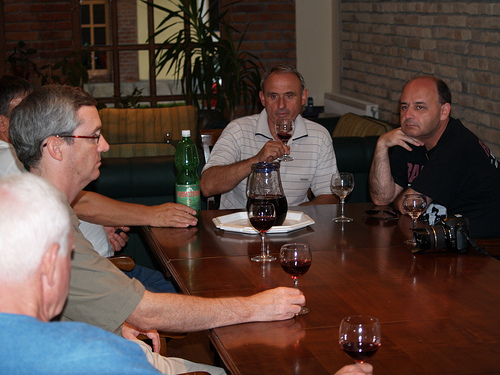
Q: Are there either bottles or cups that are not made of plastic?
A: No, there is a bottle but it is made of plastic.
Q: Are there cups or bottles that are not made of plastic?
A: No, there is a bottle but it is made of plastic.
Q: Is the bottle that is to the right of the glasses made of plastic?
A: Yes, the bottle is made of plastic.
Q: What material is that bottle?
A: The bottle is made of plastic.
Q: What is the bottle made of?
A: The bottle is made of plastic.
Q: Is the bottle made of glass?
A: No, the bottle is made of plastic.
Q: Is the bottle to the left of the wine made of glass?
A: No, the bottle is made of plastic.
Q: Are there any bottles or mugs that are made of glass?
A: No, there is a bottle but it is made of plastic.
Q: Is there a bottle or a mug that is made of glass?
A: No, there is a bottle but it is made of plastic.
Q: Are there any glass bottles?
A: No, there is a bottle but it is made of plastic.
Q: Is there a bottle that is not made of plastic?
A: No, there is a bottle but it is made of plastic.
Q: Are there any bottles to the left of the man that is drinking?
A: Yes, there is a bottle to the left of the man.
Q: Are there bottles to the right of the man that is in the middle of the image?
A: No, the bottle is to the left of the man.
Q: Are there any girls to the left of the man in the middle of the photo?
A: No, there is a bottle to the left of the man.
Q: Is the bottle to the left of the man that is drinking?
A: Yes, the bottle is to the left of the man.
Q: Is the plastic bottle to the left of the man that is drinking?
A: Yes, the bottle is to the left of the man.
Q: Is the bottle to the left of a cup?
A: No, the bottle is to the left of the man.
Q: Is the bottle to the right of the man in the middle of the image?
A: No, the bottle is to the left of the man.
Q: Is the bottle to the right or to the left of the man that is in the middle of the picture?
A: The bottle is to the left of the man.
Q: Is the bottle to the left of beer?
A: No, the bottle is to the left of the wine.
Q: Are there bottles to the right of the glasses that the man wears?
A: Yes, there is a bottle to the right of the glasses.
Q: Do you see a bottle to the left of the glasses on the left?
A: No, the bottle is to the right of the glasses.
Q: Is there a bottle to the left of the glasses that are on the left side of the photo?
A: No, the bottle is to the right of the glasses.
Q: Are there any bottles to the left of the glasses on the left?
A: No, the bottle is to the right of the glasses.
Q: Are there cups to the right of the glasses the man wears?
A: No, there is a bottle to the right of the glasses.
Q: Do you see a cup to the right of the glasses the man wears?
A: No, there is a bottle to the right of the glasses.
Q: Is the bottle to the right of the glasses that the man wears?
A: Yes, the bottle is to the right of the glasses.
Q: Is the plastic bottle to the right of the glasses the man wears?
A: Yes, the bottle is to the right of the glasses.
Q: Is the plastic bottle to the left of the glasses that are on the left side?
A: No, the bottle is to the right of the glasses.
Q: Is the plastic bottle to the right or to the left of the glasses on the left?
A: The bottle is to the right of the glasses.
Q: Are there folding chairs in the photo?
A: No, there are no folding chairs.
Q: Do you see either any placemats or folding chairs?
A: No, there are no folding chairs or placemats.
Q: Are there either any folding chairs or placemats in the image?
A: No, there are no folding chairs or placemats.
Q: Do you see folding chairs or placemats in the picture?
A: No, there are no folding chairs or placemats.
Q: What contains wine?
A: The glass contains wine.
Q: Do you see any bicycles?
A: No, there are no bicycles.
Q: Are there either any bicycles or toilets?
A: No, there are no bicycles or toilets.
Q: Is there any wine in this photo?
A: Yes, there is wine.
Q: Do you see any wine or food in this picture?
A: Yes, there is wine.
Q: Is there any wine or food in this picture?
A: Yes, there is wine.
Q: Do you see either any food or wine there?
A: Yes, there is wine.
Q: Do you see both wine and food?
A: No, there is wine but no food.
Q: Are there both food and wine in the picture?
A: No, there is wine but no food.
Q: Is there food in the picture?
A: No, there is no food.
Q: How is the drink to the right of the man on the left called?
A: The drink is wine.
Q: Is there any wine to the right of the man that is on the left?
A: Yes, there is wine to the right of the man.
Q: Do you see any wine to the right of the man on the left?
A: Yes, there is wine to the right of the man.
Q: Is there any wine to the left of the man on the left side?
A: No, the wine is to the right of the man.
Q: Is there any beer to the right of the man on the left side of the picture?
A: No, there is wine to the right of the man.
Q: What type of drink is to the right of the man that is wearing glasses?
A: The drink is wine.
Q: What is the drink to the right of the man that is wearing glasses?
A: The drink is wine.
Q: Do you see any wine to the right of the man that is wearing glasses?
A: Yes, there is wine to the right of the man.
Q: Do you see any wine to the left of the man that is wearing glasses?
A: No, the wine is to the right of the man.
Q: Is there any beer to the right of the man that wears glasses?
A: No, there is wine to the right of the man.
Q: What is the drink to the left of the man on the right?
A: The drink is wine.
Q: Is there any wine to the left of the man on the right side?
A: Yes, there is wine to the left of the man.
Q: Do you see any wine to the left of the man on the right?
A: Yes, there is wine to the left of the man.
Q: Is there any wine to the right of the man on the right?
A: No, the wine is to the left of the man.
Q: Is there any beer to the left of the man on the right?
A: No, there is wine to the left of the man.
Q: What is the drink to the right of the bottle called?
A: The drink is wine.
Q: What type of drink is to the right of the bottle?
A: The drink is wine.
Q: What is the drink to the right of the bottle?
A: The drink is wine.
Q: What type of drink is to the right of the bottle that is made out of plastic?
A: The drink is wine.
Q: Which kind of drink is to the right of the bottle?
A: The drink is wine.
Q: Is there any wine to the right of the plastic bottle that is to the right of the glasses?
A: Yes, there is wine to the right of the bottle.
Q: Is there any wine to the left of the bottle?
A: No, the wine is to the right of the bottle.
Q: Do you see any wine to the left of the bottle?
A: No, the wine is to the right of the bottle.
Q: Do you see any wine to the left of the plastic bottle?
A: No, the wine is to the right of the bottle.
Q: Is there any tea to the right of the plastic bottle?
A: No, there is wine to the right of the bottle.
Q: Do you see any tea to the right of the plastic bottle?
A: No, there is wine to the right of the bottle.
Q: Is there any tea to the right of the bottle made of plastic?
A: No, there is wine to the right of the bottle.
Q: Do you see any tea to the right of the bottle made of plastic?
A: No, there is wine to the right of the bottle.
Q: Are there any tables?
A: Yes, there is a table.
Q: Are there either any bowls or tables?
A: Yes, there is a table.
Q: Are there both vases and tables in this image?
A: No, there is a table but no vases.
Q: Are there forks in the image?
A: No, there are no forks.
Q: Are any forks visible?
A: No, there are no forks.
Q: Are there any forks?
A: No, there are no forks.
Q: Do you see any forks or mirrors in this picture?
A: No, there are no forks or mirrors.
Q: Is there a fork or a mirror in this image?
A: No, there are no forks or mirrors.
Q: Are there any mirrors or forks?
A: No, there are no forks or mirrors.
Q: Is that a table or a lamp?
A: That is a table.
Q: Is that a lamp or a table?
A: That is a table.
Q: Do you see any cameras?
A: Yes, there is a camera.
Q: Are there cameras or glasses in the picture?
A: Yes, there is a camera.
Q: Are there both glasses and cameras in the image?
A: Yes, there are both a camera and glasses.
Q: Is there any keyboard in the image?
A: No, there are no keyboards.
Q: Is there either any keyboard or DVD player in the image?
A: No, there are no keyboards or DVD players.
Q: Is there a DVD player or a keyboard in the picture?
A: No, there are no keyboards or DVD players.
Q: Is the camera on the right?
A: Yes, the camera is on the right of the image.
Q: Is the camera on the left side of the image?
A: No, the camera is on the right of the image.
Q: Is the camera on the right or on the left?
A: The camera is on the right of the image.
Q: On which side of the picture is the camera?
A: The camera is on the right of the image.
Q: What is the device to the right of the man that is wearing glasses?
A: The device is a camera.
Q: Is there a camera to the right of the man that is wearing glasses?
A: Yes, there is a camera to the right of the man.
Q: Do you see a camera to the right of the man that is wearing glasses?
A: Yes, there is a camera to the right of the man.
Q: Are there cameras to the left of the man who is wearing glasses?
A: No, the camera is to the right of the man.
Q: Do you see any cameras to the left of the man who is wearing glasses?
A: No, the camera is to the right of the man.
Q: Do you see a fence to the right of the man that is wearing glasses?
A: No, there is a camera to the right of the man.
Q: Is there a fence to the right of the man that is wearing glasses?
A: No, there is a camera to the right of the man.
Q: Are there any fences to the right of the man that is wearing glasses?
A: No, there is a camera to the right of the man.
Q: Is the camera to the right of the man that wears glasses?
A: Yes, the camera is to the right of the man.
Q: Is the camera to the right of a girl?
A: No, the camera is to the right of the man.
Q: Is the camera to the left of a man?
A: No, the camera is to the right of a man.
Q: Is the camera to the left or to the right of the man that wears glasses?
A: The camera is to the right of the man.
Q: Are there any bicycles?
A: No, there are no bicycles.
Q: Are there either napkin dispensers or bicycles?
A: No, there are no bicycles or napkin dispensers.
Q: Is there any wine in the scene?
A: Yes, there is wine.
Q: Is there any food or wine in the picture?
A: Yes, there is wine.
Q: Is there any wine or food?
A: Yes, there is wine.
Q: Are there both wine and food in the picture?
A: No, there is wine but no food.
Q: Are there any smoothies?
A: No, there are no smoothies.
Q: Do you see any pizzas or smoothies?
A: No, there are no smoothies or pizzas.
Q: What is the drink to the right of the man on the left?
A: The drink is wine.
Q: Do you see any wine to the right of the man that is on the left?
A: Yes, there is wine to the right of the man.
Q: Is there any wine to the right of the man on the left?
A: Yes, there is wine to the right of the man.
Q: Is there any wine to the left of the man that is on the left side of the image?
A: No, the wine is to the right of the man.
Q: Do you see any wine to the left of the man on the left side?
A: No, the wine is to the right of the man.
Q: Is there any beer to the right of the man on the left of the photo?
A: No, there is wine to the right of the man.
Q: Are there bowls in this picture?
A: No, there are no bowls.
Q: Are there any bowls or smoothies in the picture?
A: No, there are no bowls or smoothies.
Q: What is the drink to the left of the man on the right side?
A: The drink is wine.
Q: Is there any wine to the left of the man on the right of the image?
A: Yes, there is wine to the left of the man.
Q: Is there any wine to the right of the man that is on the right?
A: No, the wine is to the left of the man.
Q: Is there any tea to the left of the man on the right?
A: No, there is wine to the left of the man.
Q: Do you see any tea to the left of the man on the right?
A: No, there is wine to the left of the man.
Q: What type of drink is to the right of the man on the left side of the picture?
A: The drink is wine.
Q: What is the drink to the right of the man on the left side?
A: The drink is wine.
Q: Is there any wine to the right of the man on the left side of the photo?
A: Yes, there is wine to the right of the man.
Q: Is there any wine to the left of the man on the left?
A: No, the wine is to the right of the man.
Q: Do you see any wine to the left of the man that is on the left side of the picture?
A: No, the wine is to the right of the man.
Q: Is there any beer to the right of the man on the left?
A: No, there is wine to the right of the man.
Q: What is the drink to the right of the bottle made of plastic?
A: The drink is wine.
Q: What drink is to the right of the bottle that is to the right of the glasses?
A: The drink is wine.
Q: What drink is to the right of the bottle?
A: The drink is wine.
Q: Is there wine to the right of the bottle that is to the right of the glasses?
A: Yes, there is wine to the right of the bottle.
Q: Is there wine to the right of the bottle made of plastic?
A: Yes, there is wine to the right of the bottle.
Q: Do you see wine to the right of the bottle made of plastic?
A: Yes, there is wine to the right of the bottle.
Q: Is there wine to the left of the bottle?
A: No, the wine is to the right of the bottle.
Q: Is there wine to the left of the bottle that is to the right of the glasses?
A: No, the wine is to the right of the bottle.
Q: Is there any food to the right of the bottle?
A: No, there is wine to the right of the bottle.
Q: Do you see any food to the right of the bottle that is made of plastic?
A: No, there is wine to the right of the bottle.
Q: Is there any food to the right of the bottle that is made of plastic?
A: No, there is wine to the right of the bottle.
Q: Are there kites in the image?
A: No, there are no kites.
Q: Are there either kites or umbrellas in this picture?
A: No, there are no kites or umbrellas.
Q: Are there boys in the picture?
A: No, there are no boys.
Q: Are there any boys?
A: No, there are no boys.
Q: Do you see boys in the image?
A: No, there are no boys.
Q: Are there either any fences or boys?
A: No, there are no boys or fences.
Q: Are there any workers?
A: No, there are no workers.